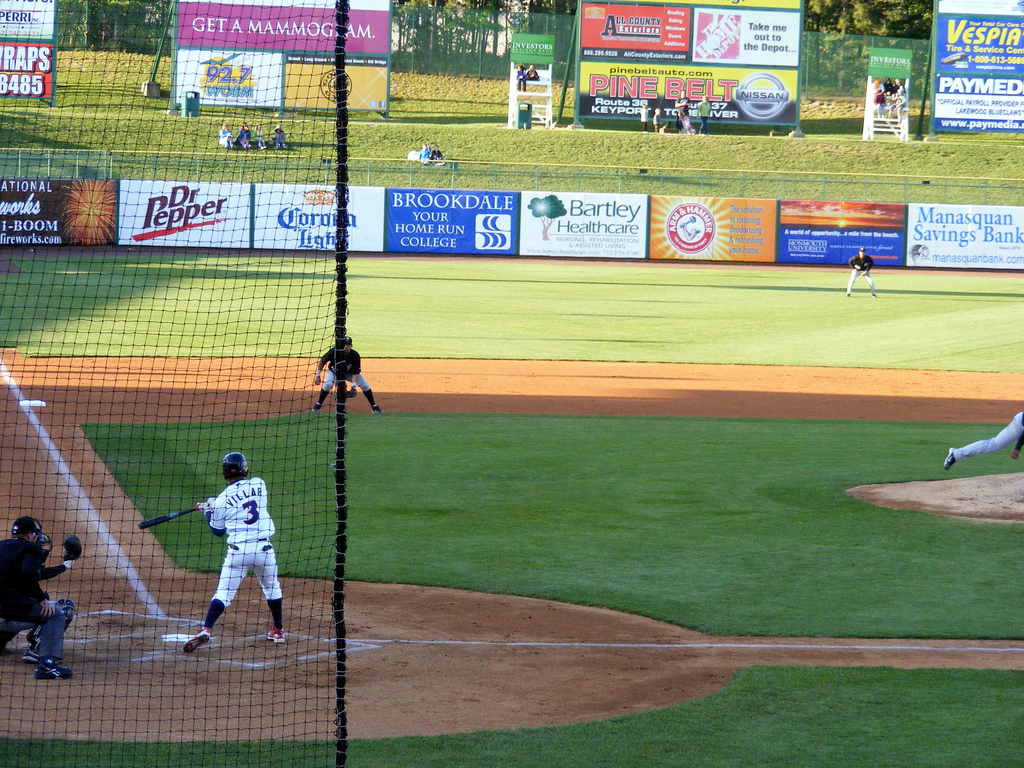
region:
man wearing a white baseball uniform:
[169, 432, 309, 666]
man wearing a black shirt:
[296, 319, 407, 444]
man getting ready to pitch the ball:
[292, 315, 411, 449]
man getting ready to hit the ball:
[147, 414, 318, 656]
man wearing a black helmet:
[2, 506, 82, 696]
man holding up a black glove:
[19, 518, 96, 670]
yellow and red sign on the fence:
[649, 187, 770, 270]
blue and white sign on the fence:
[381, 181, 525, 268]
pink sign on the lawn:
[177, 4, 405, 58]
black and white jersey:
[198, 456, 274, 573]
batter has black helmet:
[222, 439, 245, 488]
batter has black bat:
[111, 491, 239, 561]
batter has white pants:
[201, 535, 285, 596]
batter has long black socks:
[163, 582, 280, 655]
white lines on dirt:
[245, 570, 642, 748]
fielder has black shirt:
[307, 348, 374, 415]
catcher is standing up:
[0, 506, 78, 713]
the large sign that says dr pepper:
[117, 183, 253, 248]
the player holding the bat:
[138, 451, 282, 649]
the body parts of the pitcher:
[943, 411, 1021, 468]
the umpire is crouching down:
[1, 515, 71, 680]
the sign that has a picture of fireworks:
[1, 177, 119, 253]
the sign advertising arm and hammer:
[648, 192, 778, 263]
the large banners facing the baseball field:
[1, 0, 1020, 766]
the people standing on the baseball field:
[1, 244, 1019, 766]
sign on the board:
[782, 193, 893, 263]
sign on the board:
[671, 192, 777, 276]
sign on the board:
[381, 183, 519, 260]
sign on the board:
[283, 193, 370, 257]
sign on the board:
[152, 198, 245, 271]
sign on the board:
[14, 195, 107, 253]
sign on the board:
[573, 63, 801, 128]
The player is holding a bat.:
[130, 483, 242, 531]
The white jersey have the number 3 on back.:
[220, 494, 269, 527]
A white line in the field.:
[367, 610, 943, 669]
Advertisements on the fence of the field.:
[445, 190, 977, 283]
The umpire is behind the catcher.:
[13, 530, 72, 683]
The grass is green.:
[389, 256, 974, 359]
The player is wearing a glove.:
[57, 530, 103, 570]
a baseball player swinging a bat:
[134, 458, 305, 646]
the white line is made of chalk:
[24, 410, 158, 619]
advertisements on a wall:
[8, 177, 1017, 275]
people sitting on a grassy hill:
[198, 117, 303, 157]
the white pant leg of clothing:
[949, 411, 1016, 479]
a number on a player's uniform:
[223, 489, 268, 535]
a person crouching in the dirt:
[302, 337, 394, 415]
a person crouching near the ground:
[8, 521, 91, 670]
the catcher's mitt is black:
[51, 531, 89, 566]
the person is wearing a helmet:
[225, 452, 251, 485]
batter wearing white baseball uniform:
[188, 445, 312, 667]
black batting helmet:
[212, 446, 251, 492]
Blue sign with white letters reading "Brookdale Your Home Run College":
[382, 184, 520, 264]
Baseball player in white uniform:
[138, 448, 293, 655]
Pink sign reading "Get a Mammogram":
[170, 2, 393, 57]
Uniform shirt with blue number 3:
[206, 474, 277, 544]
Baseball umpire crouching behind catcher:
[1, 513, 84, 679]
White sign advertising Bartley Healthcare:
[514, 184, 645, 255]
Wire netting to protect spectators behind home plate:
[6, 0, 358, 764]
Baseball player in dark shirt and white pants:
[305, 334, 386, 412]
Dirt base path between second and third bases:
[5, 350, 1023, 434]